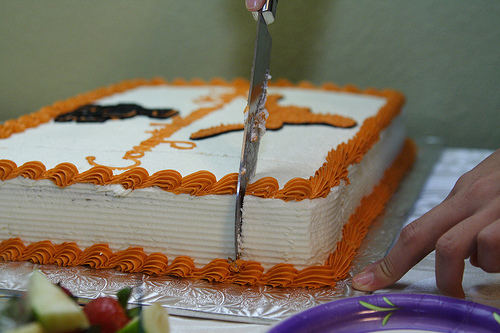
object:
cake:
[2, 77, 418, 289]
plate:
[266, 292, 499, 333]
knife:
[233, 0, 287, 268]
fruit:
[25, 266, 93, 332]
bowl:
[1, 287, 113, 332]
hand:
[354, 150, 499, 300]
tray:
[2, 130, 447, 325]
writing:
[85, 86, 249, 172]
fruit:
[83, 294, 130, 332]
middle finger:
[349, 192, 478, 292]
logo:
[189, 92, 357, 140]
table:
[2, 146, 499, 333]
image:
[55, 102, 183, 123]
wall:
[3, 1, 500, 153]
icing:
[232, 72, 267, 256]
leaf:
[116, 284, 134, 309]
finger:
[243, 0, 274, 10]